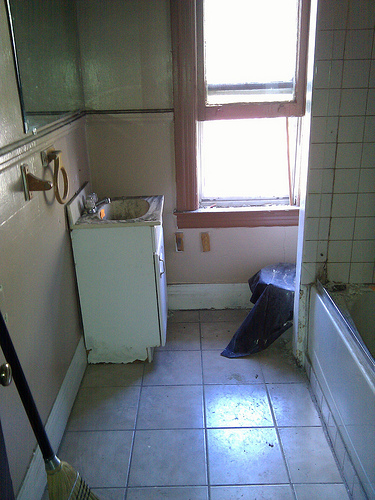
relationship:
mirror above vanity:
[29, 2, 170, 118] [79, 192, 171, 364]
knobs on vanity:
[79, 184, 98, 218] [79, 192, 171, 364]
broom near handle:
[5, 322, 111, 498] [0, 356, 12, 392]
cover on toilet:
[256, 266, 314, 325] [245, 259, 291, 349]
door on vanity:
[148, 232, 169, 348] [79, 192, 171, 364]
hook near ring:
[22, 174, 62, 197] [40, 152, 74, 202]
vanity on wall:
[79, 192, 171, 364] [31, 129, 180, 366]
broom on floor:
[5, 322, 111, 498] [71, 339, 337, 495]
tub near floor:
[327, 280, 374, 334] [71, 339, 337, 495]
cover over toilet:
[256, 266, 314, 325] [245, 259, 291, 349]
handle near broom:
[0, 356, 12, 392] [5, 322, 111, 498]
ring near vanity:
[40, 152, 74, 202] [79, 192, 171, 364]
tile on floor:
[100, 359, 334, 492] [71, 339, 337, 495]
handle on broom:
[2, 322, 57, 462] [5, 322, 111, 498]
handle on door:
[155, 257, 166, 279] [148, 232, 169, 348]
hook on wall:
[22, 174, 62, 197] [31, 129, 180, 366]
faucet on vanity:
[87, 187, 116, 219] [79, 192, 171, 364]